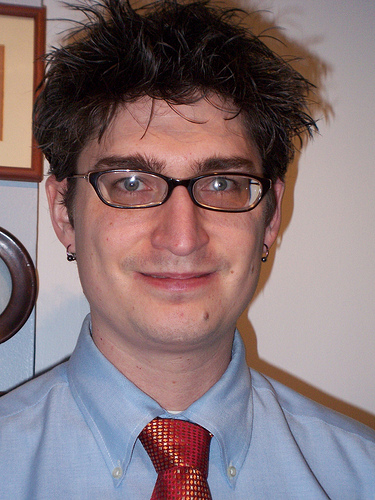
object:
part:
[300, 156, 374, 373]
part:
[66, 312, 252, 487]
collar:
[66, 312, 254, 490]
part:
[90, 312, 237, 413]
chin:
[128, 302, 223, 346]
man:
[1, 1, 374, 499]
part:
[257, 3, 329, 93]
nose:
[150, 183, 210, 257]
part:
[259, 243, 270, 264]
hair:
[32, 1, 320, 181]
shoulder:
[1, 362, 74, 499]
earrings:
[260, 243, 270, 263]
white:
[166, 409, 182, 416]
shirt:
[167, 410, 185, 413]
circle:
[0, 227, 35, 344]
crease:
[260, 375, 328, 499]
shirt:
[0, 313, 374, 499]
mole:
[203, 311, 209, 321]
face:
[71, 94, 264, 348]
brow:
[92, 152, 165, 173]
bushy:
[194, 153, 257, 173]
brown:
[0, 3, 47, 183]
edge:
[31, 6, 47, 182]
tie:
[138, 419, 211, 500]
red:
[138, 419, 213, 499]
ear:
[45, 176, 77, 254]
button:
[168, 414, 180, 421]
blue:
[1, 403, 83, 500]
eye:
[114, 175, 154, 193]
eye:
[201, 175, 239, 192]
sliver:
[168, 409, 180, 413]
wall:
[0, 0, 375, 431]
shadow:
[230, 6, 337, 125]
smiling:
[132, 265, 222, 292]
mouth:
[134, 268, 220, 293]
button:
[110, 466, 127, 483]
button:
[225, 462, 240, 483]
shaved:
[74, 255, 261, 350]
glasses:
[68, 167, 274, 213]